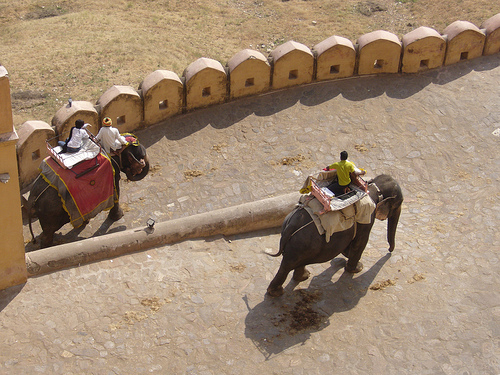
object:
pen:
[15, 15, 500, 189]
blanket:
[36, 152, 119, 229]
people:
[93, 117, 130, 154]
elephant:
[28, 133, 148, 249]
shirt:
[329, 160, 356, 186]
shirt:
[66, 123, 89, 148]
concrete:
[350, 81, 376, 155]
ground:
[0, 49, 500, 317]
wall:
[272, 49, 313, 90]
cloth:
[99, 132, 140, 157]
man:
[325, 150, 366, 195]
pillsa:
[217, 35, 269, 97]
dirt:
[183, 168, 201, 177]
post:
[24, 190, 311, 278]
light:
[0, 173, 11, 184]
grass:
[0, 0, 500, 133]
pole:
[0, 64, 28, 291]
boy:
[57, 119, 92, 153]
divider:
[146, 218, 155, 229]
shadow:
[24, 214, 126, 254]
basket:
[46, 125, 103, 169]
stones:
[226, 128, 235, 137]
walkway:
[0, 56, 499, 375]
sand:
[122, 279, 288, 357]